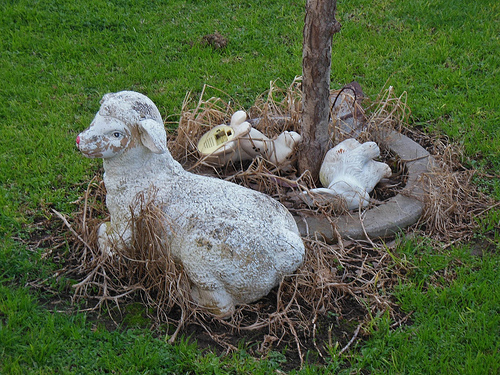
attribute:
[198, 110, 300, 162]
bunny — plastic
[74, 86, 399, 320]
statue — part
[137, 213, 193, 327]
weeds — Dead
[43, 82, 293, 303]
sheep — middle front 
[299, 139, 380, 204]
bunny — plastic, white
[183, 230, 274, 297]
thigh — part 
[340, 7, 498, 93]
grass — Green 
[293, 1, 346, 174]
tree — trunk. , back right 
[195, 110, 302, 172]
decoration — Small white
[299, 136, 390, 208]
rabbit figure — figure , twigs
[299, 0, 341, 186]
trunk — tree  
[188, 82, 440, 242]
stones — Round paver 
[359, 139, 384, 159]
paw — Two front 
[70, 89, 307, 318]
sheep — Worn white, decoration, figure , worn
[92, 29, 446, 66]
green grass — mowed, short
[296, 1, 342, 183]
trunk —  brown tree, Thin gray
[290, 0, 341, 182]
trunk — tree, thin, brown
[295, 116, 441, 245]
barrier — stone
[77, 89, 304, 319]
decoration — white sheep 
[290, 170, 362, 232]
ear — White worn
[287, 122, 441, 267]
rabbit — lying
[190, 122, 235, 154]
bottom — yellow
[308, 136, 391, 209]
bunny — white, plastic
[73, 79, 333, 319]
figure — sheep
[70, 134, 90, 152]
nose — pink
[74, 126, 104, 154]
nose — Red 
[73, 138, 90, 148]
nose — Red 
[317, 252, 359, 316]
weeds — Dead brown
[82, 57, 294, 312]
sheep. — white 